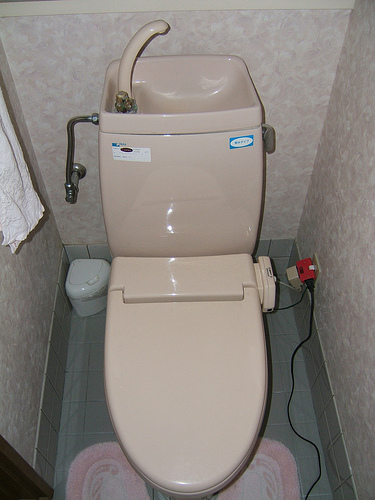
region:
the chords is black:
[298, 321, 313, 342]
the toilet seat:
[100, 316, 252, 481]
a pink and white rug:
[254, 463, 296, 498]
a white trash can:
[69, 261, 100, 294]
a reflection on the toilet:
[150, 197, 186, 238]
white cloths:
[6, 201, 29, 231]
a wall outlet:
[310, 254, 326, 274]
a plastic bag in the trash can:
[86, 289, 103, 300]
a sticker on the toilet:
[113, 144, 152, 161]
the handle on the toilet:
[262, 123, 277, 154]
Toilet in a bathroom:
[2, 2, 373, 498]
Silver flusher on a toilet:
[262, 118, 275, 152]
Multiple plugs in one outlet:
[279, 254, 326, 301]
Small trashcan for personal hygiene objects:
[59, 254, 118, 319]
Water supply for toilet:
[47, 100, 109, 216]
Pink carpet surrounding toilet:
[67, 431, 299, 497]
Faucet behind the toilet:
[110, 11, 174, 113]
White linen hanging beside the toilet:
[0, 88, 57, 259]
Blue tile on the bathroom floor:
[31, 240, 363, 497]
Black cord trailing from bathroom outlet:
[283, 278, 333, 499]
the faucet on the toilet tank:
[105, 20, 172, 102]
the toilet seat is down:
[98, 245, 267, 470]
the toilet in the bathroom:
[93, 45, 266, 495]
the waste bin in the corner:
[62, 249, 101, 313]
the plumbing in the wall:
[55, 105, 90, 210]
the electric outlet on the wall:
[305, 255, 314, 274]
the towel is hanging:
[0, 90, 47, 255]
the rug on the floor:
[54, 437, 340, 497]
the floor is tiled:
[66, 374, 101, 423]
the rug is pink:
[74, 431, 296, 498]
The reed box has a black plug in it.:
[294, 256, 314, 294]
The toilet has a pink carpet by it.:
[66, 439, 304, 499]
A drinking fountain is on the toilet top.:
[99, 18, 265, 135]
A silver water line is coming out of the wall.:
[61, 107, 97, 205]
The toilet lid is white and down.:
[104, 284, 267, 491]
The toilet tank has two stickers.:
[99, 131, 265, 256]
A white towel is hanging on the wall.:
[0, 86, 45, 253]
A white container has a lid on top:
[65, 257, 111, 317]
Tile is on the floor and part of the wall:
[27, 242, 106, 494]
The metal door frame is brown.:
[0, 434, 55, 496]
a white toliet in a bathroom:
[100, 251, 288, 492]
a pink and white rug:
[64, 447, 133, 495]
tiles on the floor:
[59, 370, 101, 433]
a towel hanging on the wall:
[5, 124, 44, 258]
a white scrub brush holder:
[70, 256, 111, 327]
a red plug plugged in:
[296, 253, 326, 292]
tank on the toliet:
[77, 47, 300, 257]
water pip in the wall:
[64, 110, 97, 207]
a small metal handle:
[252, 123, 288, 157]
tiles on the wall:
[31, 366, 61, 452]